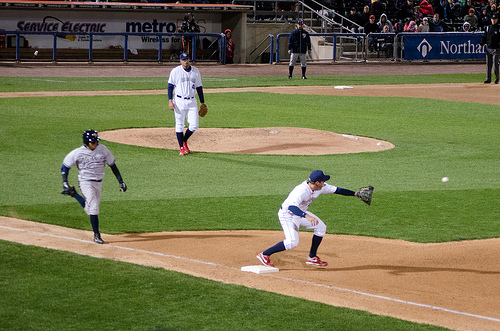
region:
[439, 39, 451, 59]
letter n on sign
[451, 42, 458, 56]
letter o on sign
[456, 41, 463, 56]
letter r on sign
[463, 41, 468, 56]
letter t on sign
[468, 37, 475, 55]
letter h on sign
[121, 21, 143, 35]
letter m on sign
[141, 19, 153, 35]
letter e on sign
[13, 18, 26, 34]
letter s on sign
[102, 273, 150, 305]
green grass on field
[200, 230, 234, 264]
brown dirt on field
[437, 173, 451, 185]
Game ball in flight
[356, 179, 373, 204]
leather glove of player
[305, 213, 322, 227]
Hand of ball player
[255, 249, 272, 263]
foot of ball player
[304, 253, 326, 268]
Foot of ball player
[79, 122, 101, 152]
Head of ball player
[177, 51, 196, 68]
Head of ball player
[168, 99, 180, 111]
Hand of ball player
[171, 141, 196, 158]
Feet of ball player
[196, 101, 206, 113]
Leather glove of ball player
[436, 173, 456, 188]
Game ball in flight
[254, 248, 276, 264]
Foot of ball player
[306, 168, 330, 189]
Head of ball player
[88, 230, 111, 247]
fot of ball player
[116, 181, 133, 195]
hand of ball player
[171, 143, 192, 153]
Feet of ball player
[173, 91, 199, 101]
Belt of ball player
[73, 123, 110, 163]
the head of a man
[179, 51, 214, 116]
the arm of a man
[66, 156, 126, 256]
the legs of a man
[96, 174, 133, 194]
the hand of a man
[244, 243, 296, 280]
the foot of a man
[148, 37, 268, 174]
a man on the grass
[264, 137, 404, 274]
a man wearing a baseball glove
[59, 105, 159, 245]
a man on a field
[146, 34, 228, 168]
a man in the outfield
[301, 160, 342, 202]
a man wearing a hat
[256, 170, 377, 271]
Baseball player holding out glove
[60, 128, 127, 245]
Player running to the base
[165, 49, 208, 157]
Pitcher standing neaer the pitcher's mound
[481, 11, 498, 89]
Umpire standing on the base line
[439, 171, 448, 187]
Baseball in the air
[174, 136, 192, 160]
Red shoes on pitcher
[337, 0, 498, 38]
Fans watching the baseball game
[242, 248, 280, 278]
Baseball player's foot on the base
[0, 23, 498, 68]
Fence at edge of field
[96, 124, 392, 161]
Dirt-covered pitcher's mound